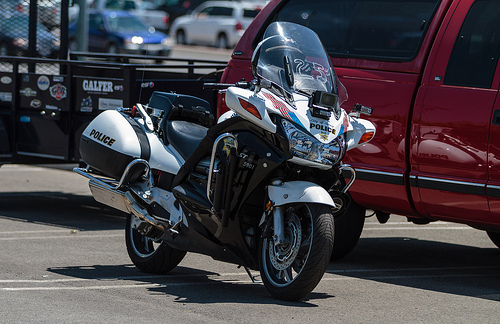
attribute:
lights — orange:
[236, 97, 262, 122]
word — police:
[88, 127, 115, 146]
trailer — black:
[3, 2, 226, 198]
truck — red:
[96, 0, 488, 302]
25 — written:
[291, 50, 333, 87]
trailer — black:
[5, 0, 270, 195]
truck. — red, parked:
[212, 1, 498, 257]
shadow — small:
[41, 251, 339, 306]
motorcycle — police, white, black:
[73, 19, 377, 303]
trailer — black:
[13, 50, 179, 158]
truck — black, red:
[289, 1, 466, 207]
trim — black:
[368, 161, 489, 198]